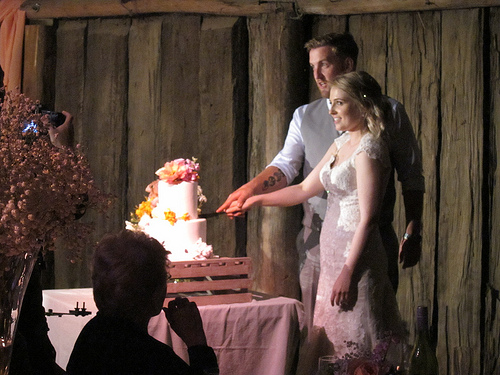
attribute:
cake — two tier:
[123, 155, 213, 262]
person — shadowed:
[62, 212, 242, 371]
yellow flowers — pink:
[128, 195, 201, 227]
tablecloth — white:
[21, 284, 303, 373]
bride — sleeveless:
[297, 69, 466, 320]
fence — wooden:
[51, 15, 498, 373]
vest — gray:
[300, 99, 392, 224]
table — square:
[71, 288, 312, 373]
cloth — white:
[45, 285, 301, 370]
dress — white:
[315, 135, 405, 369]